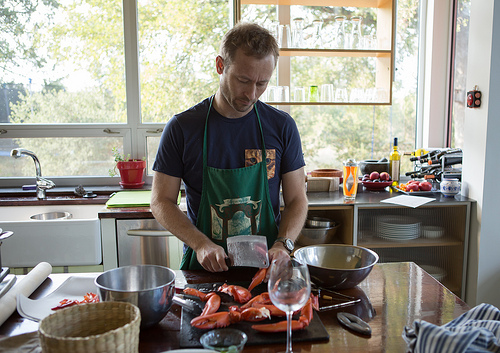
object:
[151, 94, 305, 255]
shirt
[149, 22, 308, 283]
man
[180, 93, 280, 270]
apron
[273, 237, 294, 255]
watch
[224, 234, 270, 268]
meat cleaver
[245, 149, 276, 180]
cat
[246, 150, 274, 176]
shirt pocket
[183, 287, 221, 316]
lobster claw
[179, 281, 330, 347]
cutting board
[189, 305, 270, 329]
lobster claw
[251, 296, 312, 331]
lobster claw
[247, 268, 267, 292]
lobster claw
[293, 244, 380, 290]
bowl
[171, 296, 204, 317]
tongs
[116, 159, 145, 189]
flower pot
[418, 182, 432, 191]
tomato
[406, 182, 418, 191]
tomato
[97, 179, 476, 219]
counter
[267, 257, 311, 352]
wine glass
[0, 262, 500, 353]
counter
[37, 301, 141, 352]
basket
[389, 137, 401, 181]
bottle of wine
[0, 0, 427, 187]
window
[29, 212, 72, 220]
bowl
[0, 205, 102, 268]
kitchen sink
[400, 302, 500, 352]
towel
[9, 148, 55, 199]
faucet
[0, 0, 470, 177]
tree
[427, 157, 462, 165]
bottle of wine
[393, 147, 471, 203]
rack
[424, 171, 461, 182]
bottle of wine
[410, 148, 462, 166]
bottle of wine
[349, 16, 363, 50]
glass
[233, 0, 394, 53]
shelf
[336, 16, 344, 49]
glass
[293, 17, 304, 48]
glass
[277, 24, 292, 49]
glass